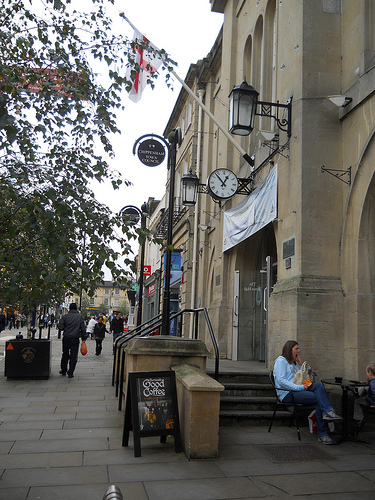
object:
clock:
[206, 168, 238, 201]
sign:
[138, 139, 166, 167]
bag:
[81, 340, 88, 356]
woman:
[273, 340, 343, 445]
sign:
[122, 370, 181, 457]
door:
[232, 270, 240, 362]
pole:
[161, 139, 176, 335]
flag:
[124, 29, 167, 103]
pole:
[119, 12, 255, 168]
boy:
[350, 363, 374, 428]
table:
[320, 378, 372, 444]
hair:
[282, 340, 299, 364]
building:
[123, 1, 371, 452]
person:
[58, 303, 87, 378]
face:
[209, 169, 237, 197]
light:
[180, 168, 199, 207]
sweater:
[273, 355, 306, 402]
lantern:
[228, 75, 293, 138]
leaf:
[127, 80, 134, 90]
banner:
[222, 163, 278, 252]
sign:
[143, 265, 151, 276]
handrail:
[196, 307, 219, 380]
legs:
[341, 391, 349, 440]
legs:
[307, 380, 333, 414]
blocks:
[42, 427, 121, 443]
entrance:
[227, 223, 277, 373]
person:
[93, 316, 110, 356]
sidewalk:
[1, 332, 375, 500]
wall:
[226, 0, 309, 340]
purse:
[293, 361, 317, 385]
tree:
[2, 187, 79, 339]